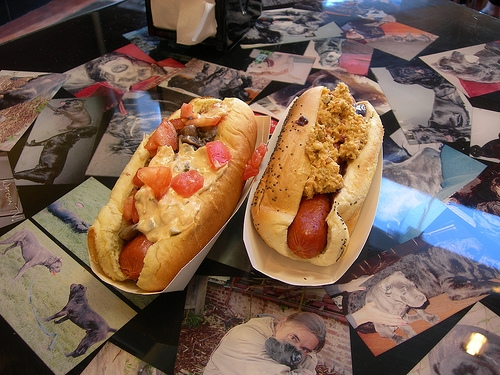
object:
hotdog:
[83, 95, 257, 292]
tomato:
[205, 138, 233, 172]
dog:
[0, 226, 63, 280]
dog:
[44, 281, 118, 362]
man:
[202, 310, 327, 374]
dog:
[262, 336, 308, 373]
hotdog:
[249, 80, 385, 266]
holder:
[240, 96, 383, 287]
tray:
[88, 112, 275, 296]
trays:
[241, 96, 384, 287]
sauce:
[301, 79, 367, 199]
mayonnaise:
[205, 96, 232, 112]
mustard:
[300, 82, 372, 201]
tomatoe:
[135, 165, 175, 200]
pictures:
[416, 40, 499, 99]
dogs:
[406, 123, 461, 145]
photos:
[30, 175, 195, 310]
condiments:
[136, 133, 231, 243]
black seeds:
[286, 194, 292, 199]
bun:
[306, 98, 383, 267]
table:
[0, 0, 498, 374]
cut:
[182, 182, 204, 198]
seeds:
[288, 151, 293, 156]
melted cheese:
[132, 140, 227, 242]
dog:
[363, 271, 439, 344]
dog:
[309, 39, 344, 71]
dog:
[344, 243, 499, 334]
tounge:
[56, 100, 70, 107]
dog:
[45, 200, 95, 233]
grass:
[31, 177, 153, 309]